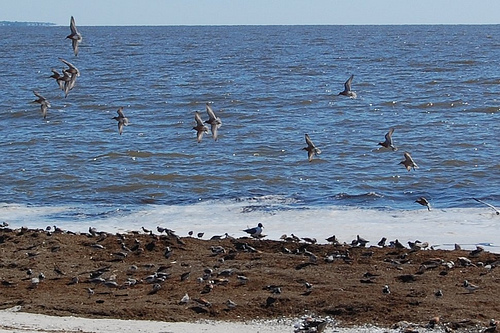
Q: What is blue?
A: Water.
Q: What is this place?
A: Ocean.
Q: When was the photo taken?
A: Daytime.